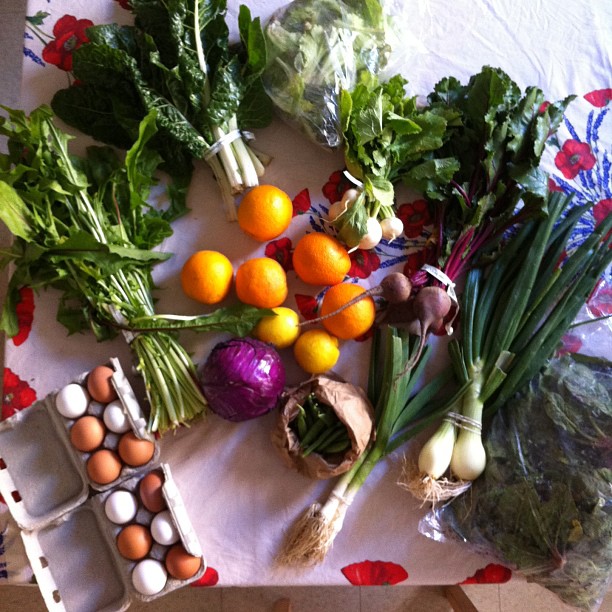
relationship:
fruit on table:
[235, 256, 288, 308] [1, 0, 611, 588]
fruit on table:
[181, 250, 234, 304] [1, 0, 611, 588]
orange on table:
[235, 181, 296, 244] [1, 0, 611, 588]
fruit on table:
[320, 282, 376, 339] [1, 0, 611, 588]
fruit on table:
[292, 232, 351, 285] [1, 0, 611, 588]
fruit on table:
[238, 185, 293, 242] [1, 0, 611, 588]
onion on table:
[195, 334, 287, 421] [1, 0, 611, 588]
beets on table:
[295, 62, 576, 398] [1, 0, 611, 588]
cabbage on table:
[317, 65, 465, 254] [1, 0, 611, 588]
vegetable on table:
[257, 1, 394, 150] [1, 0, 611, 588]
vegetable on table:
[51, 3, 267, 222] [1, 0, 611, 588]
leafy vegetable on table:
[0, 104, 280, 439] [1, 0, 611, 588]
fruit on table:
[293, 326, 341, 373] [1, 0, 611, 588]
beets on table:
[299, 62, 576, 375] [1, 0, 611, 588]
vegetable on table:
[11, 191, 156, 314] [34, 141, 595, 610]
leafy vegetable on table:
[6, 110, 179, 416] [34, 141, 595, 610]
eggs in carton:
[77, 357, 209, 609] [10, 377, 210, 590]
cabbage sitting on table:
[277, 10, 424, 232] [10, 64, 587, 575]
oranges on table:
[188, 171, 377, 301] [10, 64, 587, 575]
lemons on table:
[264, 301, 356, 379] [35, 165, 487, 481]